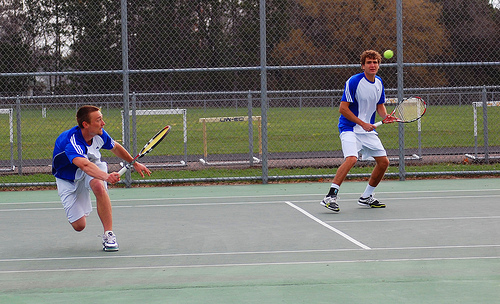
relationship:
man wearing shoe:
[311, 51, 407, 211] [355, 195, 385, 206]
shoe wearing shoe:
[355, 195, 385, 206] [319, 191, 341, 211]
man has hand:
[311, 51, 407, 211] [355, 115, 377, 137]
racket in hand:
[365, 92, 431, 134] [355, 115, 377, 137]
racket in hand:
[365, 92, 431, 134] [381, 112, 401, 126]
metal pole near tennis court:
[240, 25, 317, 175] [1, 169, 498, 301]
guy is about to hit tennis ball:
[321, 45, 435, 220] [381, 45, 397, 61]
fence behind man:
[2, 0, 499, 187] [51, 104, 153, 253]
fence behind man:
[2, 0, 499, 187] [311, 51, 407, 211]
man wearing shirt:
[311, 51, 407, 211] [341, 71, 400, 137]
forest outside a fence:
[6, 5, 484, 101] [2, 0, 499, 187]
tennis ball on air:
[381, 45, 397, 61] [2, 2, 497, 300]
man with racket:
[270, 38, 415, 221] [112, 103, 204, 175]